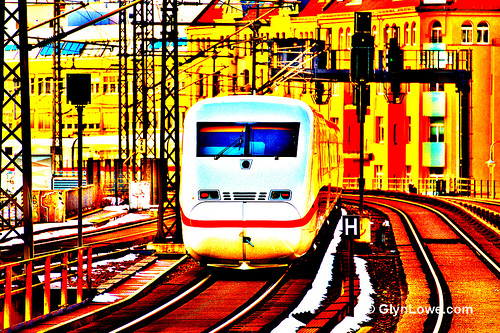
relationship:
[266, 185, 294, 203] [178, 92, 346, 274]
light on train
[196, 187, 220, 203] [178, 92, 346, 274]
light on train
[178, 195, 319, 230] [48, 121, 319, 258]
stripe on train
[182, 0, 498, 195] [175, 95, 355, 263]
building behind train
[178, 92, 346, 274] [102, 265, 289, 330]
train on track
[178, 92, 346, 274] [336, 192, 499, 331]
train on track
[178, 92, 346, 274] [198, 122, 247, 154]
train has window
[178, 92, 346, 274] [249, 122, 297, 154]
train has window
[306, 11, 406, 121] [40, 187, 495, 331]
lights on track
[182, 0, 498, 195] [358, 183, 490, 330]
building next to track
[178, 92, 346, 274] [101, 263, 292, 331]
train has rails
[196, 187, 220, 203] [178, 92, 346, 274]
light on front train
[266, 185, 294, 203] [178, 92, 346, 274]
light on front train